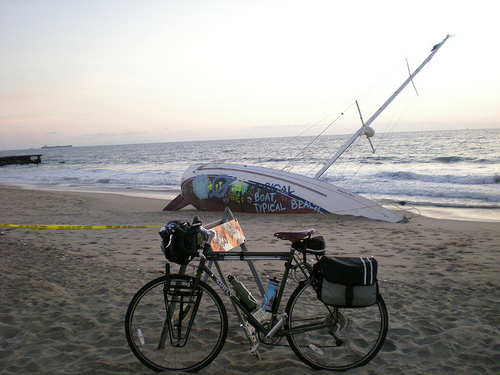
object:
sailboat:
[160, 33, 457, 225]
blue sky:
[4, 0, 499, 196]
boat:
[161, 160, 402, 222]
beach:
[29, 188, 148, 246]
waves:
[93, 152, 500, 203]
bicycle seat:
[272, 228, 314, 243]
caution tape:
[3, 224, 162, 231]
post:
[156, 207, 278, 362]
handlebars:
[188, 216, 214, 254]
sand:
[3, 199, 495, 372]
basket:
[157, 218, 200, 264]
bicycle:
[123, 203, 389, 373]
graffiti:
[249, 189, 287, 215]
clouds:
[0, 0, 500, 145]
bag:
[316, 254, 381, 308]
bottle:
[260, 276, 279, 310]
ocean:
[0, 130, 497, 207]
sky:
[0, 0, 500, 151]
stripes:
[359, 257, 375, 286]